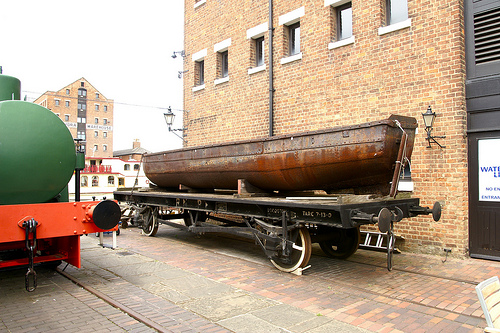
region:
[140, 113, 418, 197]
Rusty boat on a carrier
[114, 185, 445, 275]
Carrier that's holding the boat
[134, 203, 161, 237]
Front left wheel of the carrier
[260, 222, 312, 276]
Back left wheel of the carrier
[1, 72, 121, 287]
Green tank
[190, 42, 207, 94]
Small square window on the brick building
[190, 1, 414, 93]
Group of windows on the brick building.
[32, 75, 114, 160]
Tall building on the other side of the lake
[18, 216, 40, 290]
Large black chain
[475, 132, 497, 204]
White sign with letters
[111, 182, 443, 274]
Carrier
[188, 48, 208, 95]
Small square window of the brick building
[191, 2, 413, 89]
Row of windows on the brick building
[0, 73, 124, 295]
Green gas tank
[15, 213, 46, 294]
Small black chain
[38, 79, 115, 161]
Large building on the other side of the lake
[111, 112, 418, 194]
Rusty boat on the carrier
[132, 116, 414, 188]
The rusted out boat on the trailer.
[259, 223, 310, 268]
The left back wheel of the trailer the boat is on.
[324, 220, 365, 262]
The right back wheel of the trailer the rusted boat is on.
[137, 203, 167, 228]
The left front wheel of the trailer the rusted boat is on.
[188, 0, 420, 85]
The windows above the rusted boat.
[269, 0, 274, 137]
The pole on the building to the right of the rusted boat.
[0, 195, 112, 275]
The orange trailer to the left of the rusted boat.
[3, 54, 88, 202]
The green item on the orange trailer.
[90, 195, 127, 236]
The black circle on the orange trailer.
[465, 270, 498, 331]
The chair in the right hand corner.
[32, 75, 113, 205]
a tall brick building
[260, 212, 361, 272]
a pair of wheels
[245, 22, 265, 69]
a small window on a building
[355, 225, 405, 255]
part of a silver ladder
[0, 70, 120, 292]
a green and orange train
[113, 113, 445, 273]
a rusted train car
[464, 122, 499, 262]
part of a brown door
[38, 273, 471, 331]
part of a brick road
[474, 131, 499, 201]
a white sign with blue letters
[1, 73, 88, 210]
a green tank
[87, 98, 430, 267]
a large rusty boat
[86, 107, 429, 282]
a large boat on a trailer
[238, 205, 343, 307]
white wheels on a black trailer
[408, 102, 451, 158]
a lamp on a brick wall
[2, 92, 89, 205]
a forest green water tank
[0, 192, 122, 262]
an orange trailer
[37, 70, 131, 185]
a brick building with windows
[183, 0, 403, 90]
a row of six windows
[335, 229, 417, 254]
a ladder leaning against the building